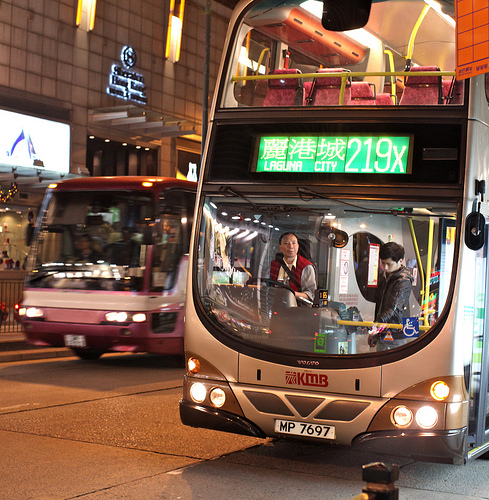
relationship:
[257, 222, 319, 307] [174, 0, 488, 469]
bus driver driving bus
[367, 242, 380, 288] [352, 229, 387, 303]
paper on window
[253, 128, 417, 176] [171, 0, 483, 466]
green light on bus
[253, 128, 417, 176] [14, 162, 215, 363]
green light on bus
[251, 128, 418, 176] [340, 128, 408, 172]
green light says 219x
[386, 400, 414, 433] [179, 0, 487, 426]
headlight on bus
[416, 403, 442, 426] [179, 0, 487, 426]
light on bus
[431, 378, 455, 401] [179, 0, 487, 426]
light on bus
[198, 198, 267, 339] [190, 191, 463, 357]
reflection in windshield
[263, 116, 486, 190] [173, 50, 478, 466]
sign on front of bus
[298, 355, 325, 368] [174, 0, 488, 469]
medallion from bus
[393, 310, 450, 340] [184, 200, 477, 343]
sticker in windshield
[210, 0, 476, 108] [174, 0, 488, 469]
top level of bus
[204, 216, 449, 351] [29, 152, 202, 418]
windshield on bus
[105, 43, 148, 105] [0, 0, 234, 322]
black sign above building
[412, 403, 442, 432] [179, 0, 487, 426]
light on bus